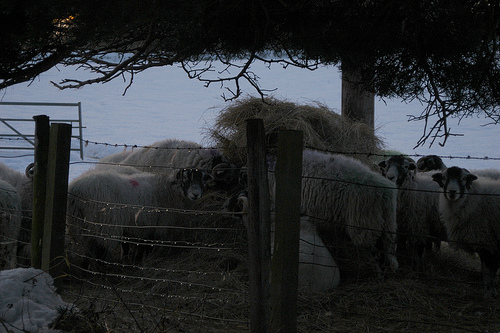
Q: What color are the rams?
A: White.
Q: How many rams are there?
A: 8.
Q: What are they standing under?
A: A tree.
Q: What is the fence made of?
A: Barbed wire.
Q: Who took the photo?
A: The photographer.